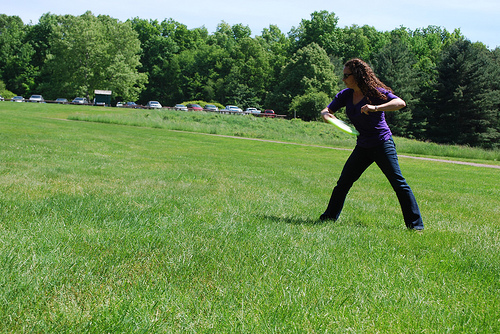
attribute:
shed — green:
[88, 85, 113, 110]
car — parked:
[28, 84, 44, 101]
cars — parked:
[1, 87, 285, 120]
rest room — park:
[92, 86, 114, 110]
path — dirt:
[205, 130, 499, 170]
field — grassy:
[0, 95, 498, 331]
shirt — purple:
[329, 90, 393, 138]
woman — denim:
[319, 57, 426, 225]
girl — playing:
[314, 56, 431, 236]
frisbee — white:
[320, 112, 360, 139]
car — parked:
[188, 101, 203, 111]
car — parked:
[225, 103, 244, 113]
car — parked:
[70, 94, 92, 105]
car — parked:
[142, 98, 164, 108]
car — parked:
[174, 102, 188, 111]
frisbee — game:
[321, 112, 355, 134]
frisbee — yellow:
[323, 113, 355, 134]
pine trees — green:
[381, 38, 496, 140]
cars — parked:
[256, 107, 275, 119]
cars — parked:
[222, 99, 247, 116]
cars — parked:
[204, 97, 219, 114]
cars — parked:
[93, 93, 110, 106]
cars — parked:
[14, 90, 29, 105]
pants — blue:
[321, 131, 424, 228]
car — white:
[144, 96, 167, 108]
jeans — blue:
[319, 127, 422, 225]